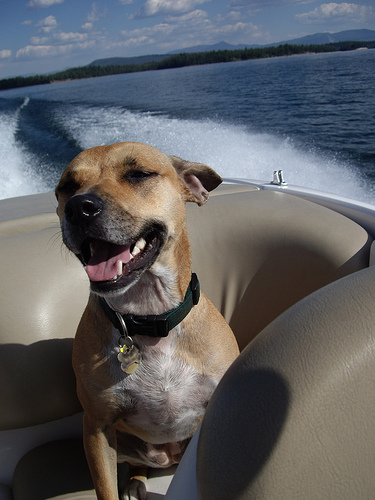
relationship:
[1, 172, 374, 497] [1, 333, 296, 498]
seat has shadow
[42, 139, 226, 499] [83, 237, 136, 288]
dog has tongue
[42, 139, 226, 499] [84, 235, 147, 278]
dog has teeth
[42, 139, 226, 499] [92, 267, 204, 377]
dog has collar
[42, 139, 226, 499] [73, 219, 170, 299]
dog has lip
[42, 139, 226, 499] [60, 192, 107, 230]
dog has nose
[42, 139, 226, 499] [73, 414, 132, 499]
dog has leg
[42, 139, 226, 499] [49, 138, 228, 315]
dog has head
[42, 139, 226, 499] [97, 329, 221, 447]
dog has chest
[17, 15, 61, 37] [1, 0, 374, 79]
cloud in sky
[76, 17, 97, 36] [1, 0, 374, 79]
cloud in sky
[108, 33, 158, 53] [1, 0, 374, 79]
cloud in sky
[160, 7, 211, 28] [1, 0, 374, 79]
cloud in sky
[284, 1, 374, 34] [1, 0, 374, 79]
cloud in sky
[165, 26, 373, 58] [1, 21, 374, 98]
hills in background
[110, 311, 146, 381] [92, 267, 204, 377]
dog tags on collar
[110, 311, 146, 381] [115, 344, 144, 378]
dog tags are shaped like bone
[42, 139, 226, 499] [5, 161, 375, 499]
dog sitting on boat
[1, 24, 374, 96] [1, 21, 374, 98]
sky line in background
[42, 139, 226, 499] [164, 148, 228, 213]
dog has ear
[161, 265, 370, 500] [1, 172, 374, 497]
edge of seat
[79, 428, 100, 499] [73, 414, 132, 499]
edge of leg